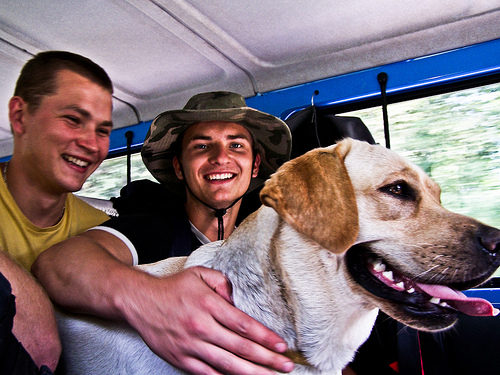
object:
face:
[182, 121, 252, 201]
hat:
[140, 91, 292, 194]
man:
[28, 91, 295, 374]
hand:
[113, 266, 295, 374]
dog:
[53, 137, 500, 375]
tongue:
[402, 276, 500, 317]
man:
[0, 51, 116, 375]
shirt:
[0, 173, 111, 272]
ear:
[259, 148, 359, 254]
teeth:
[366, 258, 448, 307]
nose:
[478, 225, 500, 260]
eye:
[377, 179, 416, 199]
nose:
[210, 144, 232, 165]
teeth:
[206, 173, 234, 180]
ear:
[173, 155, 185, 180]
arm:
[30, 210, 173, 317]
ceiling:
[1, 1, 500, 131]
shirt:
[82, 179, 268, 266]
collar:
[286, 349, 314, 366]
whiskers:
[412, 245, 465, 286]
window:
[325, 82, 500, 278]